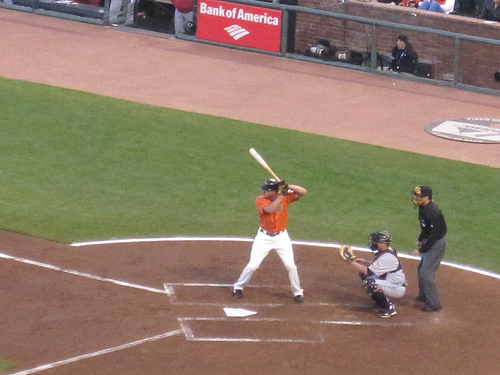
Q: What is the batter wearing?
A: An orange jersey.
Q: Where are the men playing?
A: A baseball field.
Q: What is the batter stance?
A: Ready to swing.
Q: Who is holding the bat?
A: The batter.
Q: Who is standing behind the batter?
A: The catcher.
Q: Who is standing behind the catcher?
A: The umpire.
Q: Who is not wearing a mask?
A: The batter.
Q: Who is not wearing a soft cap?
A: The batter.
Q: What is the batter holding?
A: A wooden bat.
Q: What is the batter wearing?
A: An orange shirt and white pants.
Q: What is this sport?
A: Baseball.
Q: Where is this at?
A: Baseball field.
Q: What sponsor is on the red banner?
A: Bank of America.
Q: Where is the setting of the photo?
A: Baseball field.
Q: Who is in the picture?
A: 4 males.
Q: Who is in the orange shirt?
A: The batter.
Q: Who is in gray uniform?
A: Catcher.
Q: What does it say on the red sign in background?
A: Bank of America.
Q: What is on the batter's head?
A: Helmet.